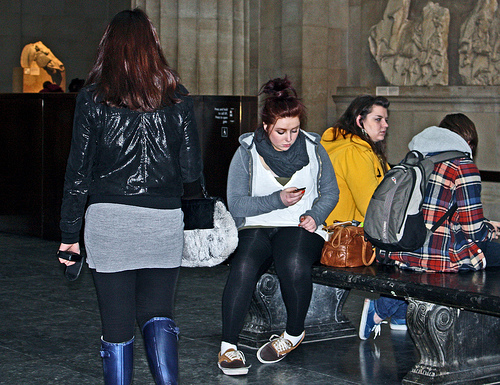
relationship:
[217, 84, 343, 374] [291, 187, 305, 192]
girl looking at phone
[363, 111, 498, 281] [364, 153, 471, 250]
girl wearing backpack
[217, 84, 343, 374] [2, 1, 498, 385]
girl in museum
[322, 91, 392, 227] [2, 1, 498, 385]
girl in museum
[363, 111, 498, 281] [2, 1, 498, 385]
girl in museum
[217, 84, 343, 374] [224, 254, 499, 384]
girl on bech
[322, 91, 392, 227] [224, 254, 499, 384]
girl on bech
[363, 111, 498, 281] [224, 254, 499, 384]
girl on bech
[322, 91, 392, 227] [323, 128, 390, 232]
girl wearing sweater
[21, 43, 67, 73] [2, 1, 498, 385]
statue in museum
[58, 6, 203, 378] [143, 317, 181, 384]
girl wearing shoe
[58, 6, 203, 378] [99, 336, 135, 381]
girl wearing shoe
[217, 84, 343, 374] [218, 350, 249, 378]
girl wearing shoe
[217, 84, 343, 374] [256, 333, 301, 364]
girl wearing shoe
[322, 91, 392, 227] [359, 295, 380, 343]
girl wearing shoe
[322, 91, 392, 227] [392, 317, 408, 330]
girl wearing shoe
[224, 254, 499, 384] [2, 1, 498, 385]
bech in museum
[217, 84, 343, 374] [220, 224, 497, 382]
girl sitting on bench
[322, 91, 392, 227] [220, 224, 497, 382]
girl sitting on bench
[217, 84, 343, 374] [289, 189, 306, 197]
girl holding phone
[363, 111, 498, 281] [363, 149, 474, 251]
girl wearing a backpack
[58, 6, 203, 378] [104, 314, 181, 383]
girl wearing boots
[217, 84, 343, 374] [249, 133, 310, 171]
girl wearing a scarf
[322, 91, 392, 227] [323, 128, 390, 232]
girl wearing a sweater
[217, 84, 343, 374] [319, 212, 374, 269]
girl sitting next to brown bag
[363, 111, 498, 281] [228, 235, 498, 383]
girl sharing a bench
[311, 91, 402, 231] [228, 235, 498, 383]
person sharing a bench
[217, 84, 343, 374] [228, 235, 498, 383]
girl sharing a bench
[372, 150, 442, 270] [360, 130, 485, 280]
backpack on a person's back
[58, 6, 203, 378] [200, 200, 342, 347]
girl wearing pants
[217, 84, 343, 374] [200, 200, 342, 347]
girl wearing pants